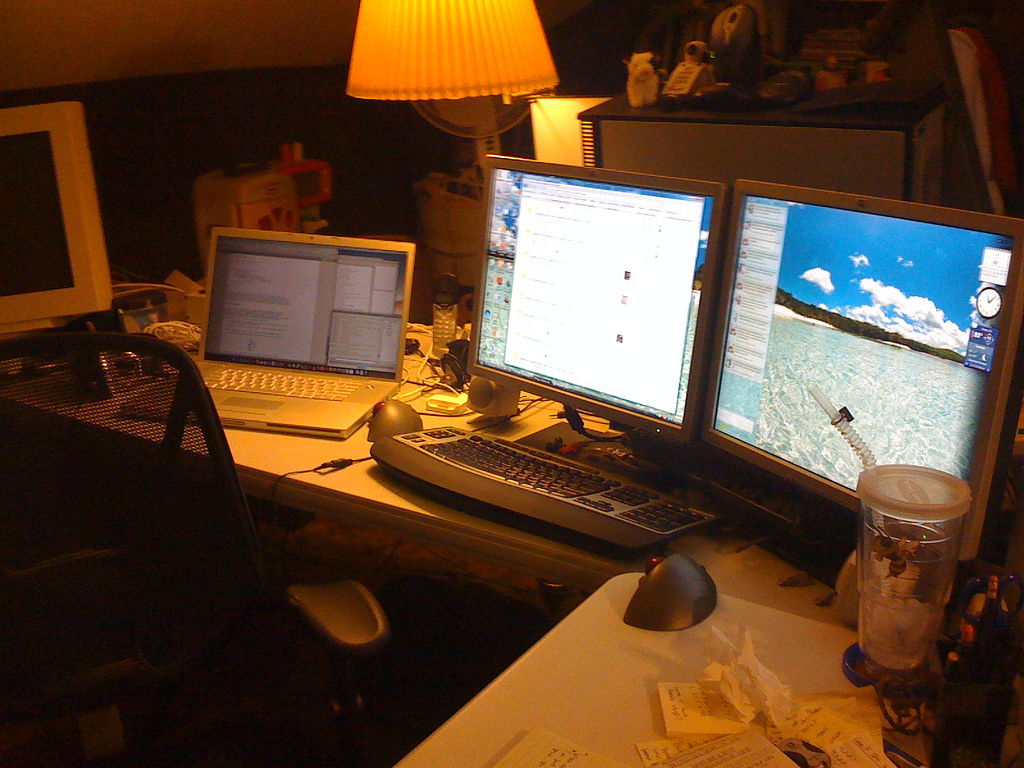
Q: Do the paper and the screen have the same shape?
A: Yes, both the paper and the screen are square.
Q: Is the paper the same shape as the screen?
A: Yes, both the paper and the screen are square.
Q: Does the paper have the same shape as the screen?
A: Yes, both the paper and the screen are square.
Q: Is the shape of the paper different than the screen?
A: No, both the paper and the screen are square.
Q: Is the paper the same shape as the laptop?
A: Yes, both the paper and the laptop are square.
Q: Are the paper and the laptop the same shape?
A: Yes, both the paper and the laptop are square.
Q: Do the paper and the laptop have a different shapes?
A: No, both the paper and the laptop are square.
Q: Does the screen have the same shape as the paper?
A: Yes, both the screen and the paper are square.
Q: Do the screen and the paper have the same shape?
A: Yes, both the screen and the paper are square.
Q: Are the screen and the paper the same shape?
A: Yes, both the screen and the paper are square.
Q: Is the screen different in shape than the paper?
A: No, both the screen and the paper are square.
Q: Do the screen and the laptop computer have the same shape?
A: Yes, both the screen and the laptop computer are square.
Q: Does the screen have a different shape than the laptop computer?
A: No, both the screen and the laptop computer are square.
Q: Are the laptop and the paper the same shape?
A: Yes, both the laptop and the paper are square.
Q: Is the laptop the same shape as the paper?
A: Yes, both the laptop and the paper are square.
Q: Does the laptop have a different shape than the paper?
A: No, both the laptop and the paper are square.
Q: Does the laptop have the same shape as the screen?
A: Yes, both the laptop and the screen are square.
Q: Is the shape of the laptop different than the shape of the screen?
A: No, both the laptop and the screen are square.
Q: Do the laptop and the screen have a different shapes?
A: No, both the laptop and the screen are square.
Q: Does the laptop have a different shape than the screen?
A: No, both the laptop and the screen are square.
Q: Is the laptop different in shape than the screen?
A: No, both the laptop and the screen are square.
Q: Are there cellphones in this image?
A: No, there are no cellphones.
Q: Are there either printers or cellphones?
A: No, there are no cellphones or printers.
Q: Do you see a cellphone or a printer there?
A: No, there are no cell phones or printers.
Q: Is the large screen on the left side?
A: Yes, the screen is on the left of the image.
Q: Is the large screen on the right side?
A: No, the screen is on the left of the image.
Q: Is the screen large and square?
A: Yes, the screen is large and square.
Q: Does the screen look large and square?
A: Yes, the screen is large and square.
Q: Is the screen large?
A: Yes, the screen is large.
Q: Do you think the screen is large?
A: Yes, the screen is large.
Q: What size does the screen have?
A: The screen has large size.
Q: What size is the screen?
A: The screen is large.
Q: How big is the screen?
A: The screen is large.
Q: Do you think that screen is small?
A: No, the screen is large.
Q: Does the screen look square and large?
A: Yes, the screen is square and large.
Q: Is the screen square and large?
A: Yes, the screen is square and large.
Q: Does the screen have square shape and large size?
A: Yes, the screen is square and large.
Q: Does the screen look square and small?
A: No, the screen is square but large.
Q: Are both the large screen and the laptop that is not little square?
A: Yes, both the screen and the laptop computer are square.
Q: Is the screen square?
A: Yes, the screen is square.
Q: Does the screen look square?
A: Yes, the screen is square.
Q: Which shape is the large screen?
A: The screen is square.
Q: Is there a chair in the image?
A: Yes, there is a chair.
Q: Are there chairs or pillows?
A: Yes, there is a chair.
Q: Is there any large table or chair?
A: Yes, there is a large chair.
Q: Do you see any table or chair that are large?
A: Yes, the chair is large.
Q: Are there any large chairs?
A: Yes, there is a large chair.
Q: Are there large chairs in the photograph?
A: Yes, there is a large chair.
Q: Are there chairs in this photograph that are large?
A: Yes, there is a chair that is large.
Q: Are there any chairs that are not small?
A: Yes, there is a large chair.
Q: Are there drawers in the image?
A: No, there are no drawers.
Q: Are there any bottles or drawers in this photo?
A: No, there are no drawers or bottles.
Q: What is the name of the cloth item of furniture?
A: The piece of furniture is a chair.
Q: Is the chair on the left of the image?
A: Yes, the chair is on the left of the image.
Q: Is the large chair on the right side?
A: No, the chair is on the left of the image.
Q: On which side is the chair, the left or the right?
A: The chair is on the left of the image.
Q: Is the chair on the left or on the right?
A: The chair is on the left of the image.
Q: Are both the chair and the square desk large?
A: Yes, both the chair and the desk are large.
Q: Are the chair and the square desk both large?
A: Yes, both the chair and the desk are large.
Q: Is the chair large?
A: Yes, the chair is large.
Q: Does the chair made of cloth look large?
A: Yes, the chair is large.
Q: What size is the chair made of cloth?
A: The chair is large.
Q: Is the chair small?
A: No, the chair is large.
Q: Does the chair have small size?
A: No, the chair is large.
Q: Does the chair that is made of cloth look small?
A: No, the chair is large.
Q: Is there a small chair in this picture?
A: No, there is a chair but it is large.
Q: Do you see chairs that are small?
A: No, there is a chair but it is large.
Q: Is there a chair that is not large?
A: No, there is a chair but it is large.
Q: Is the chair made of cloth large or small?
A: The chair is large.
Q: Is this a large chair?
A: Yes, this is a large chair.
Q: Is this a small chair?
A: No, this is a large chair.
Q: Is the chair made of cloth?
A: Yes, the chair is made of cloth.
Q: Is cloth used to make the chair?
A: Yes, the chair is made of cloth.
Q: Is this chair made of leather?
A: No, the chair is made of cloth.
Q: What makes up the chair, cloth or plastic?
A: The chair is made of cloth.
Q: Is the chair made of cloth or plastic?
A: The chair is made of cloth.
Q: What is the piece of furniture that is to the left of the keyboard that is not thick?
A: The piece of furniture is a chair.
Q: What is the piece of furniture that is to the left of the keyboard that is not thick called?
A: The piece of furniture is a chair.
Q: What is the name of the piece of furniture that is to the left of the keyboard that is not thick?
A: The piece of furniture is a chair.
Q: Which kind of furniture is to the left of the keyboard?
A: The piece of furniture is a chair.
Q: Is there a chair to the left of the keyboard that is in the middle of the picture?
A: Yes, there is a chair to the left of the keyboard.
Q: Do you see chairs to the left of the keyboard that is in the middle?
A: Yes, there is a chair to the left of the keyboard.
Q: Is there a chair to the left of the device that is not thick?
A: Yes, there is a chair to the left of the keyboard.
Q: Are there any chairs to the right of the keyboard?
A: No, the chair is to the left of the keyboard.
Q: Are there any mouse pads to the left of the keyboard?
A: No, there is a chair to the left of the keyboard.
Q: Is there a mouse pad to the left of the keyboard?
A: No, there is a chair to the left of the keyboard.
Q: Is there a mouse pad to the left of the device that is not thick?
A: No, there is a chair to the left of the keyboard.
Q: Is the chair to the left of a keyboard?
A: Yes, the chair is to the left of a keyboard.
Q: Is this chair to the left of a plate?
A: No, the chair is to the left of a keyboard.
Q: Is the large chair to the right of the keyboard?
A: No, the chair is to the left of the keyboard.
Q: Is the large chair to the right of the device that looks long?
A: No, the chair is to the left of the keyboard.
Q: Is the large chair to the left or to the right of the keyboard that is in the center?
A: The chair is to the left of the keyboard.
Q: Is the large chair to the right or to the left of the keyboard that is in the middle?
A: The chair is to the left of the keyboard.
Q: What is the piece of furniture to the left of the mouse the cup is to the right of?
A: The piece of furniture is a chair.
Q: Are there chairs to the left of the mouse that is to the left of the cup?
A: Yes, there is a chair to the left of the computer mouse.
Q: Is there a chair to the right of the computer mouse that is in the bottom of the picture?
A: No, the chair is to the left of the computer mouse.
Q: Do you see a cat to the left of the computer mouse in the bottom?
A: No, there is a chair to the left of the mouse.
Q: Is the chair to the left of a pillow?
A: No, the chair is to the left of the computer mouse.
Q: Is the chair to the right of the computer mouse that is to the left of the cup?
A: No, the chair is to the left of the mouse.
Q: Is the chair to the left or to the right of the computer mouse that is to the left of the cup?
A: The chair is to the left of the computer mouse.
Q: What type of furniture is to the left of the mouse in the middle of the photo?
A: The piece of furniture is a chair.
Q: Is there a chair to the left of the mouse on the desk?
A: Yes, there is a chair to the left of the computer mouse.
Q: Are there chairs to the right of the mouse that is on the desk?
A: No, the chair is to the left of the computer mouse.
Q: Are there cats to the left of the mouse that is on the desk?
A: No, there is a chair to the left of the computer mouse.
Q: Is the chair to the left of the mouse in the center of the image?
A: Yes, the chair is to the left of the computer mouse.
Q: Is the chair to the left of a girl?
A: No, the chair is to the left of the computer mouse.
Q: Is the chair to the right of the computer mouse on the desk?
A: No, the chair is to the left of the computer mouse.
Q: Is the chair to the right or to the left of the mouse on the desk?
A: The chair is to the left of the mouse.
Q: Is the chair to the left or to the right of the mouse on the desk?
A: The chair is to the left of the mouse.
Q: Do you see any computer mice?
A: Yes, there is a computer mouse.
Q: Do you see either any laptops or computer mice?
A: Yes, there is a computer mouse.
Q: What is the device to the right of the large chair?
A: The device is a computer mouse.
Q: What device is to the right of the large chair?
A: The device is a computer mouse.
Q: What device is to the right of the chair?
A: The device is a computer mouse.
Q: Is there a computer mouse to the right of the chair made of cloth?
A: Yes, there is a computer mouse to the right of the chair.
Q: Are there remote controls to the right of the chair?
A: No, there is a computer mouse to the right of the chair.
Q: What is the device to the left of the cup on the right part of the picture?
A: The device is a computer mouse.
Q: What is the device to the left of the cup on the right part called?
A: The device is a computer mouse.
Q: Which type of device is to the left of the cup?
A: The device is a computer mouse.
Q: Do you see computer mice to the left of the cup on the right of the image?
A: Yes, there is a computer mouse to the left of the cup.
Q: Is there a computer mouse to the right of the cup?
A: No, the computer mouse is to the left of the cup.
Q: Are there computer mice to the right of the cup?
A: No, the computer mouse is to the left of the cup.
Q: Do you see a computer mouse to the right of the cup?
A: No, the computer mouse is to the left of the cup.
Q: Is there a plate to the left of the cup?
A: No, there is a computer mouse to the left of the cup.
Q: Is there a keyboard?
A: Yes, there is a keyboard.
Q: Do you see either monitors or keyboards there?
A: Yes, there is a keyboard.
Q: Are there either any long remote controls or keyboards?
A: Yes, there is a long keyboard.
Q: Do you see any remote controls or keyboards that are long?
A: Yes, the keyboard is long.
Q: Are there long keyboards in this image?
A: Yes, there is a long keyboard.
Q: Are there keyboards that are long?
A: Yes, there is a keyboard that is long.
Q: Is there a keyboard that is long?
A: Yes, there is a keyboard that is long.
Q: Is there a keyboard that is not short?
A: Yes, there is a long keyboard.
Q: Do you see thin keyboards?
A: Yes, there is a thin keyboard.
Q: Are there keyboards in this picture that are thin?
A: Yes, there is a keyboard that is thin.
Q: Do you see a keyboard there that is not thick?
A: Yes, there is a thin keyboard.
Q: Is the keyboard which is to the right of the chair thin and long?
A: Yes, the keyboard is thin and long.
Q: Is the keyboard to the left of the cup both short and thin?
A: No, the keyboard is thin but long.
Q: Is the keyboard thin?
A: Yes, the keyboard is thin.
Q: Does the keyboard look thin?
A: Yes, the keyboard is thin.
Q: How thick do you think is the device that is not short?
A: The keyboard is thin.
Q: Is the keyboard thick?
A: No, the keyboard is thin.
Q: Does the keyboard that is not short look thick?
A: No, the keyboard is thin.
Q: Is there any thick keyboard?
A: No, there is a keyboard but it is thin.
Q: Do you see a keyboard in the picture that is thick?
A: No, there is a keyboard but it is thin.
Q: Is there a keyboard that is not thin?
A: No, there is a keyboard but it is thin.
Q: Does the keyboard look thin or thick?
A: The keyboard is thin.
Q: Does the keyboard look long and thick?
A: No, the keyboard is long but thin.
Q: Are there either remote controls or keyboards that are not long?
A: No, there is a keyboard but it is long.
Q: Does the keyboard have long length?
A: Yes, the keyboard is long.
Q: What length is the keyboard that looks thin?
A: The keyboard is long.